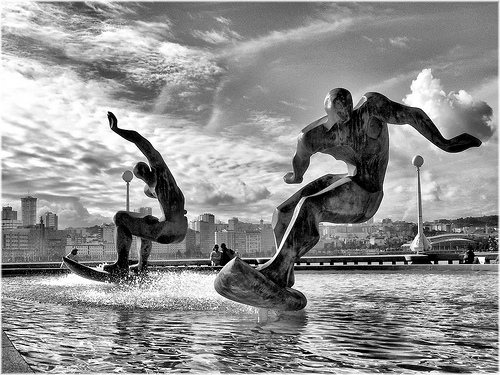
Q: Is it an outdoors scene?
A: Yes, it is outdoors.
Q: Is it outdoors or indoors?
A: It is outdoors.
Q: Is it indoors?
A: No, it is outdoors.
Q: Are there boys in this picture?
A: No, there are no boys.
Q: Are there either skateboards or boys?
A: No, there are no boys or skateboards.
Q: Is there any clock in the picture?
A: No, there are no clocks.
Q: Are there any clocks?
A: No, there are no clocks.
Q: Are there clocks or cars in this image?
A: No, there are no clocks or cars.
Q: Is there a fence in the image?
A: No, there are no fences.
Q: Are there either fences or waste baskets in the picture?
A: No, there are no fences or waste baskets.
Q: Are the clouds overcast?
A: Yes, the clouds are overcast.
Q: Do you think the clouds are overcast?
A: Yes, the clouds are overcast.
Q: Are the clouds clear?
A: No, the clouds are overcast.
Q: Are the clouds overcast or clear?
A: The clouds are overcast.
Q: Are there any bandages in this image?
A: No, there are no bandages.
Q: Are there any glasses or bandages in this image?
A: No, there are no bandages or glasses.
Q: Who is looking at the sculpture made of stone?
A: The couple is looking at the sculpture.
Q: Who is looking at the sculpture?
A: The couple is looking at the sculpture.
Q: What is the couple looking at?
A: The couple is looking at the sculpture.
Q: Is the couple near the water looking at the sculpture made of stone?
A: Yes, the couple is looking at the sculpture.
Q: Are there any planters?
A: No, there are no planters.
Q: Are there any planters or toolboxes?
A: No, there are no planters or toolboxes.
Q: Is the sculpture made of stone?
A: Yes, the sculpture is made of stone.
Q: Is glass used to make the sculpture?
A: No, the sculpture is made of stone.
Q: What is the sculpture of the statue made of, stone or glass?
A: The sculpture is made of stone.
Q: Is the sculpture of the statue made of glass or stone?
A: The sculpture is made of stone.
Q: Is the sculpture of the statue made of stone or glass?
A: The sculpture is made of stone.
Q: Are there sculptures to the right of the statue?
A: Yes, there is a sculpture to the right of the statue.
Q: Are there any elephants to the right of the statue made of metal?
A: No, there is a sculpture to the right of the statue.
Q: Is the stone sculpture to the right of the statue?
A: Yes, the sculpture is to the right of the statue.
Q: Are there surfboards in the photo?
A: Yes, there is a surfboard.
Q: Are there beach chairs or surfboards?
A: Yes, there is a surfboard.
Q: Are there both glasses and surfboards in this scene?
A: No, there is a surfboard but no glasses.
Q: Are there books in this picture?
A: No, there are no books.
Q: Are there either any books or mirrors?
A: No, there are no books or mirrors.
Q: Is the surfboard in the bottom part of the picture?
A: Yes, the surfboard is in the bottom of the image.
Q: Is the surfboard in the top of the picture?
A: No, the surfboard is in the bottom of the image.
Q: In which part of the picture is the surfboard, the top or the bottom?
A: The surfboard is in the bottom of the image.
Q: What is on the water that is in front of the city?
A: The surfboard is on the water.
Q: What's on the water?
A: The surfboard is on the water.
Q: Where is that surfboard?
A: The surfboard is on the water.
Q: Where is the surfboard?
A: The surfboard is on the water.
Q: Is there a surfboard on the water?
A: Yes, there is a surfboard on the water.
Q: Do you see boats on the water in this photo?
A: No, there is a surfboard on the water.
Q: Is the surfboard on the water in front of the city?
A: Yes, the surfboard is on the water.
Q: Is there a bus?
A: No, there are no buses.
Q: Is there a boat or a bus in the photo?
A: No, there are no buses or boats.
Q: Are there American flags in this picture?
A: No, there are no American flags.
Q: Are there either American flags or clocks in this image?
A: No, there are no American flags or clocks.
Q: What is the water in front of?
A: The water is in front of the city.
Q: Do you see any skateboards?
A: No, there are no skateboards.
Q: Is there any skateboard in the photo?
A: No, there are no skateboards.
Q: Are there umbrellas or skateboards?
A: No, there are no skateboards or umbrellas.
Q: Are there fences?
A: No, there are no fences.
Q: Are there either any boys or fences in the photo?
A: No, there are no fences or boys.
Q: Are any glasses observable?
A: No, there are no glasses.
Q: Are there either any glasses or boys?
A: No, there are no glasses or boys.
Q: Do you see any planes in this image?
A: No, there are no planes.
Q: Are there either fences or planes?
A: No, there are no planes or fences.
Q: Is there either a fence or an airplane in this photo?
A: No, there are no airplanes or fences.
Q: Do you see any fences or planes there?
A: No, there are no planes or fences.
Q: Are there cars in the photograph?
A: No, there are no cars.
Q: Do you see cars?
A: No, there are no cars.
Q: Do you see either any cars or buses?
A: No, there are no cars or buses.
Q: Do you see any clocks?
A: No, there are no clocks.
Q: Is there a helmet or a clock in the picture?
A: No, there are no clocks or helmets.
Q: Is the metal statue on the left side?
A: Yes, the statue is on the left of the image.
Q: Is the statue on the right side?
A: No, the statue is on the left of the image.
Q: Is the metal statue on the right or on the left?
A: The statue is on the left of the image.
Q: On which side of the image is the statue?
A: The statue is on the left of the image.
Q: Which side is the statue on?
A: The statue is on the left of the image.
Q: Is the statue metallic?
A: Yes, the statue is metallic.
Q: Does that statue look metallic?
A: Yes, the statue is metallic.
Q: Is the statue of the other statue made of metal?
A: Yes, the statue is made of metal.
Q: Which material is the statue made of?
A: The statue is made of metal.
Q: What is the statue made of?
A: The statue is made of metal.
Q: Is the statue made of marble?
A: No, the statue is made of metal.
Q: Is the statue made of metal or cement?
A: The statue is made of metal.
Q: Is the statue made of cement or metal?
A: The statue is made of metal.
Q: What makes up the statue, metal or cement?
A: The statue is made of metal.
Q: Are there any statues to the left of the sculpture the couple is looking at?
A: Yes, there is a statue to the left of the sculpture.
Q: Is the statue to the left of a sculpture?
A: Yes, the statue is to the left of a sculpture.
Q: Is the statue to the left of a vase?
A: No, the statue is to the left of a sculpture.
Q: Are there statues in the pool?
A: Yes, there is a statue in the pool.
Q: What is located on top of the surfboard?
A: The statue is on top of the surfboard.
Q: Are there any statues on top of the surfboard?
A: Yes, there is a statue on top of the surfboard.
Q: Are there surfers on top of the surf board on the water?
A: No, there is a statue on top of the surfboard.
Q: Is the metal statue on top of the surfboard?
A: Yes, the statue is on top of the surfboard.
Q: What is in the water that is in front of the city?
A: The statue is in the water.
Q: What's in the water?
A: The statue is in the water.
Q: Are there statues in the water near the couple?
A: Yes, there is a statue in the water.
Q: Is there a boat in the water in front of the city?
A: No, there is a statue in the water.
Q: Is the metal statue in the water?
A: Yes, the statue is in the water.